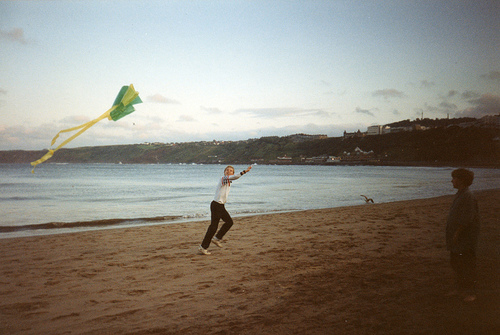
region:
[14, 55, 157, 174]
green and yellow kite in the air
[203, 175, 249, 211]
man's shirt is white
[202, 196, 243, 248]
man's pants are black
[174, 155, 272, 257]
man is flying a kite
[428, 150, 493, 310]
boy is watching the man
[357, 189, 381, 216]
bird out on the sand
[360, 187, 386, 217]
bird's wings are spread upwards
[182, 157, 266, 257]
the man is looking back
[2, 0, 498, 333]
man and boy out on beach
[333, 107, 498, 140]
houses up on hill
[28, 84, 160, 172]
a kite in the air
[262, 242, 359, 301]
the sand is brown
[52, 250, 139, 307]
the sand on the beach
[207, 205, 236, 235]
women is wearing black pants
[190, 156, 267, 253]
boy is flying a kite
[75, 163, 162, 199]
the water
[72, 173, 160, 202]
the water is blue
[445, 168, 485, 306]
a man standing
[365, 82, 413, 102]
clouds in the sky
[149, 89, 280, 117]
white clouds in the sky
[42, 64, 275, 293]
a boy flying a kite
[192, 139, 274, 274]
a boy running on a beach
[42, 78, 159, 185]
a green and yellow kite in the air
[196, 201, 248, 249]
a boy wearing black pants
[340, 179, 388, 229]
a bird landing on a beach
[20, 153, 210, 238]
the ocean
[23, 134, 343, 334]
a beach by the ocean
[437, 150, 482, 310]
a boy standing on a beach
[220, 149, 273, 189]
a boy with his arm stretched out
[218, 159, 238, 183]
a boy with blonde hair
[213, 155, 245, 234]
person flying kite on beach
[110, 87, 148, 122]
green kite in mid air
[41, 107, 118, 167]
long yellow kite tail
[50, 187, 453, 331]
sandy beach below people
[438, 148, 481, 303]
little boy standing on right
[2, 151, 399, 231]
body of water on left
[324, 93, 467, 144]
buildings on hill to the right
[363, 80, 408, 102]
gray clouds in the sky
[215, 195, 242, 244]
black pants of woman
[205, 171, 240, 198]
white shirt of woman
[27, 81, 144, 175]
kite in the air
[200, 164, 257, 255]
person running on the sand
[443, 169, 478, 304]
person standing on sand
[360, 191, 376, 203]
seagull next to water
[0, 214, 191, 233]
small wave on shore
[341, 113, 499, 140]
houses in the distance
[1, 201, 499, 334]
footprints on the sand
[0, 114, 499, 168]
hills in the background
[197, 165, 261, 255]
person wearing dark pants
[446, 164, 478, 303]
boy barefoot on the beach